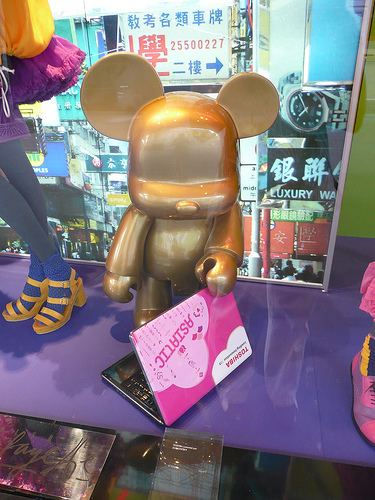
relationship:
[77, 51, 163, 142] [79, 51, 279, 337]
ear of statue